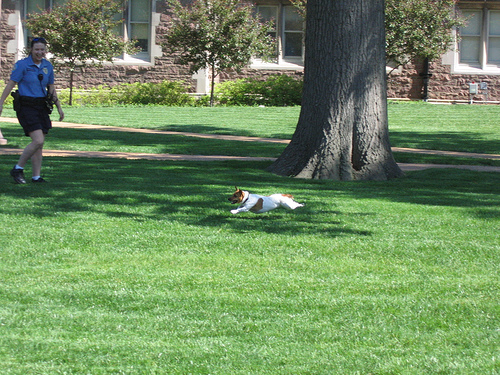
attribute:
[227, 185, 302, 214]
dog — brown, white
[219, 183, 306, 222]
dog — small, airborne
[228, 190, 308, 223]
dog — brown, white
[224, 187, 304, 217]
dog — brown, white, jumping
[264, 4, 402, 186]
tree — large, big, brown